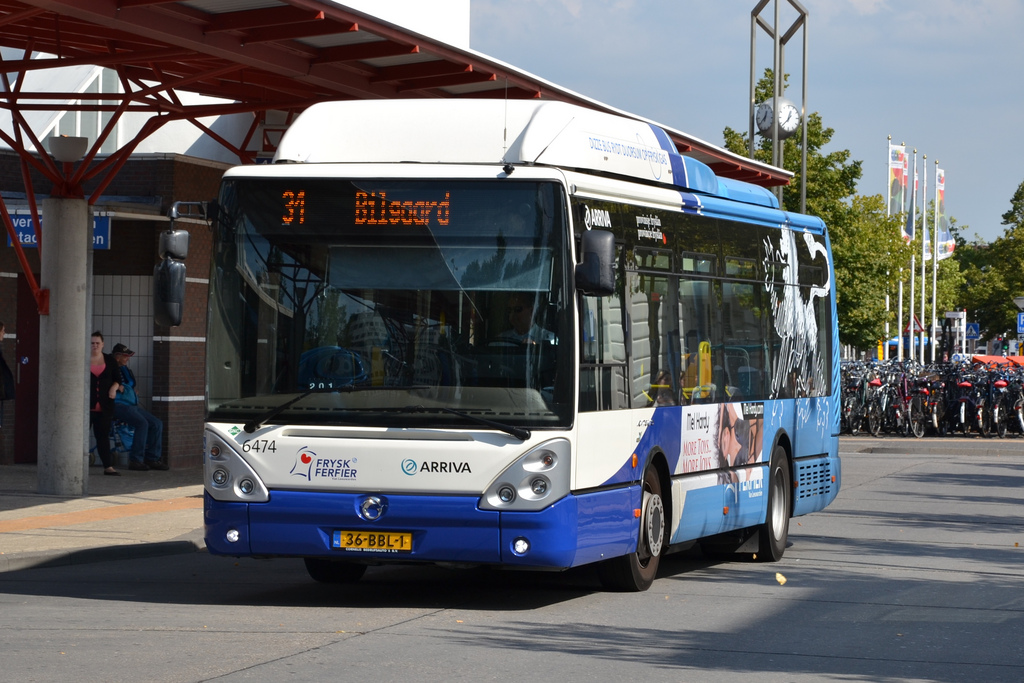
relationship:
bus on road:
[175, 90, 972, 607] [2, 423, 1017, 668]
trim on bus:
[674, 158, 832, 232] [203, 97, 840, 591]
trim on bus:
[521, 165, 688, 211] [203, 97, 840, 591]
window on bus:
[208, 175, 574, 433] [203, 97, 840, 591]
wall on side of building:
[76, 208, 150, 463] [201, 98, 846, 588]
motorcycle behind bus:
[987, 355, 1013, 431] [203, 97, 840, 591]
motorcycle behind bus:
[951, 357, 971, 424] [203, 97, 840, 591]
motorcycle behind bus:
[944, 361, 975, 435] [203, 97, 840, 591]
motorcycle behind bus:
[979, 346, 1012, 429] [203, 97, 840, 591]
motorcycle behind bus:
[864, 363, 886, 430] [203, 97, 840, 591]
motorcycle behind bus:
[948, 351, 974, 432] [203, 97, 840, 591]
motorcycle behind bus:
[946, 350, 970, 441] [203, 97, 840, 591]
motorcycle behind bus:
[944, 351, 971, 429] [203, 97, 840, 591]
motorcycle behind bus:
[944, 346, 971, 424] [203, 97, 840, 591]